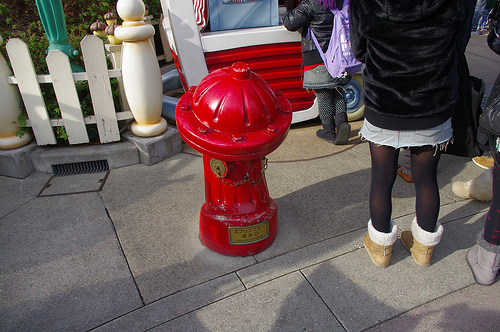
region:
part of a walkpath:
[305, 249, 341, 287]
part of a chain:
[223, 165, 260, 199]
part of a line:
[248, 267, 272, 294]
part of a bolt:
[206, 162, 225, 182]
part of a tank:
[121, 78, 166, 140]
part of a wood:
[83, 90, 115, 141]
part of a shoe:
[366, 232, 393, 276]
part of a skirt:
[378, 115, 423, 157]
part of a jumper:
[391, 61, 431, 104]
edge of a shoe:
[465, 246, 477, 263]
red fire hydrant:
[172, 57, 294, 257]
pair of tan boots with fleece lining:
[359, 216, 446, 268]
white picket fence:
[1, 35, 120, 149]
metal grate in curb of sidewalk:
[41, 153, 114, 179]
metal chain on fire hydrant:
[211, 160, 266, 187]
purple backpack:
[312, 3, 365, 79]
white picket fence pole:
[110, 0, 169, 137]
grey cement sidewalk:
[6, 177, 181, 328]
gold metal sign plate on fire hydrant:
[216, 217, 272, 247]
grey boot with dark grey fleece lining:
[463, 225, 498, 287]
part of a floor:
[272, 264, 338, 319]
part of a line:
[191, 263, 225, 296]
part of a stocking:
[368, 168, 402, 214]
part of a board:
[76, 80, 136, 152]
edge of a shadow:
[331, 262, 359, 285]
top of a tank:
[218, 72, 254, 129]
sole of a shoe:
[340, 116, 357, 139]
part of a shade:
[199, 262, 241, 313]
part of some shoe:
[371, 232, 396, 264]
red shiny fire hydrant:
[182, 68, 297, 268]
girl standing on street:
[335, 1, 450, 268]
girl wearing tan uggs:
[363, 202, 438, 274]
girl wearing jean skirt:
[353, 98, 454, 164]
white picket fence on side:
[5, 37, 132, 157]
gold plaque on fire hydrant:
[224, 222, 270, 244]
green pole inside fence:
[30, 0, 71, 47]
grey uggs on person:
[461, 227, 499, 287]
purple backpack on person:
[302, 6, 356, 79]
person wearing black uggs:
[311, 110, 353, 150]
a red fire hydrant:
[173, 63, 276, 258]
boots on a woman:
[345, 215, 450, 260]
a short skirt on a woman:
[350, 105, 470, 151]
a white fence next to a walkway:
[5, 30, 120, 140]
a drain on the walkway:
[45, 155, 125, 185]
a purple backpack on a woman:
[306, 0, 371, 75]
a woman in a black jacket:
[275, 0, 355, 135]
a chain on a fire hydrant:
[208, 152, 278, 188]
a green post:
[32, 3, 99, 87]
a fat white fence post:
[108, 1, 181, 138]